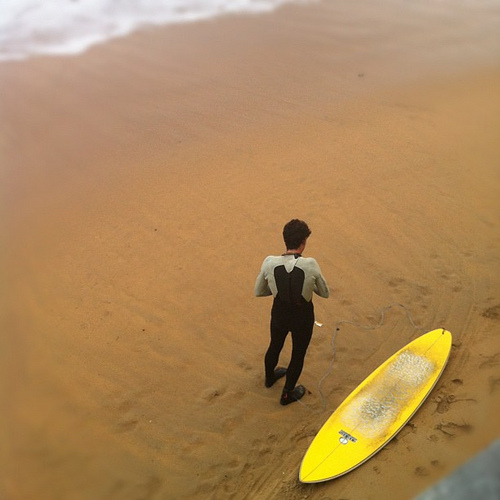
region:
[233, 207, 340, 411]
person stands on the sand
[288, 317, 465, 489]
a surfboard next toa man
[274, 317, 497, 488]
surfboard is yellow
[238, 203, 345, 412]
man wears a wetsuit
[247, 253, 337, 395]
wetsuit is gray and black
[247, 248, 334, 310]
sleeves of wetsuit are gary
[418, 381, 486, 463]
footprints on the sand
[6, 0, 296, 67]
sea water on the sand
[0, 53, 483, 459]
sand of the beach is wet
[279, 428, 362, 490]
nose of surfboard is pointy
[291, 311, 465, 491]
A well used yellow surfboard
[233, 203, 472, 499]
Man standing next to surfboard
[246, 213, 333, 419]
Man in black and white wetsuit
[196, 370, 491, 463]
Foot prints in the sand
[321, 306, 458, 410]
Gray cord attached to surfboard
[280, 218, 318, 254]
Man has short black hair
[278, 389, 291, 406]
Little red spot on back of ankle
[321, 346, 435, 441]
Worn patch on surfboard is white and brown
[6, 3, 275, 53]
Water coming up on sand is white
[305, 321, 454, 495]
There is a stripe down the center of the board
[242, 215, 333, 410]
Man stands in sand.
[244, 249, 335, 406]
Man wearing a wetsuit.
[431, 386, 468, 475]
Feet print in the sand.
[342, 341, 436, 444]
wax on the board.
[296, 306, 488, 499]
A yellow surf board.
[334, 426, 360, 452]
A logo on the board.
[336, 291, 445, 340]
The boards leg strap.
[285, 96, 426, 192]
Sand on the beach.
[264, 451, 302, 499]
Lines in the sand.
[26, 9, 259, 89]
The waves coming in.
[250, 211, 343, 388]
man wearing a wetsuit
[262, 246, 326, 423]
black and grey wetsuit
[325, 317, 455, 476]
worn out yellow surfboard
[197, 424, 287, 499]
footprints in the sand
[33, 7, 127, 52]
white seafoam by shore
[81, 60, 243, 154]
smooth tan sand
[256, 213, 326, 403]
man standing in sand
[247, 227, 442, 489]
man standing next to surfboard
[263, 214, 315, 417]
man with short brown hair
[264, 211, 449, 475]
man and surfboard on sand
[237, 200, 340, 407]
surfer on the sand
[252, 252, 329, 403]
black and grey wetsuit on a man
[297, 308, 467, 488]
yellow surfboard on the sand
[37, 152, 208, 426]
brown sand near the ocean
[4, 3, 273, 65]
water rolling in from the ocean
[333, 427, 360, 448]
logo on a surfboard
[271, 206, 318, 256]
back of head of a surfer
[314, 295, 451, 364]
rope to a surfboard in sand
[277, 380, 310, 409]
right foot with rope attached